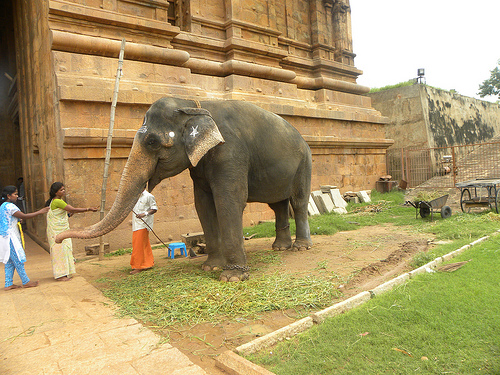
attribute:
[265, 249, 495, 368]
grass — green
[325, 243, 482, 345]
grass — green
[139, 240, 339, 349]
grass — green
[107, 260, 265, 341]
grass — green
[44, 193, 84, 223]
shirt — yellow, lime green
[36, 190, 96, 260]
sarong — light yellow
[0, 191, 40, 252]
shirt — white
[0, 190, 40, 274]
design — blue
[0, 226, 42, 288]
pants — blue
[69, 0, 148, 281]
bamboo pole — long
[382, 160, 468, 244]
wheelbarrow — full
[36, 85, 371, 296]
elephant — large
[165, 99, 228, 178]
ear — decorated with white designs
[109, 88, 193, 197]
face — decorated with white designs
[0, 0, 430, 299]
building — large, brown, stone, ornamental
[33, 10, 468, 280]
elephant — standing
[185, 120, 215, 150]
star — white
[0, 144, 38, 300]
indian outfit — white, blue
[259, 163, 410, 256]
pavers — concrete, stacked